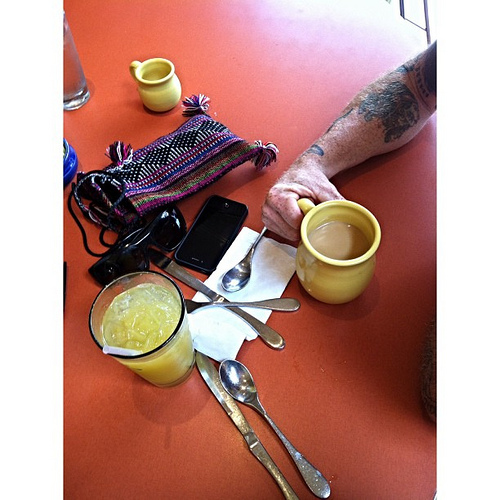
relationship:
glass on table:
[86, 268, 195, 386] [63, 0, 435, 498]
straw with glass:
[102, 345, 143, 356] [86, 268, 195, 386]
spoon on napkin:
[220, 225, 265, 291] [188, 227, 295, 362]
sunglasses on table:
[86, 205, 188, 283] [63, 0, 435, 498]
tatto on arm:
[301, 45, 435, 160] [256, 39, 438, 244]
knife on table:
[193, 350, 303, 499] [63, 0, 435, 498]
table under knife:
[63, 0, 435, 498] [193, 350, 303, 499]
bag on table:
[74, 91, 278, 223] [75, 14, 415, 483]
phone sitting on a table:
[164, 174, 253, 284] [63, 0, 435, 498]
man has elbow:
[262, 30, 465, 260] [387, 47, 437, 136]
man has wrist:
[261, 39, 437, 241] [290, 138, 343, 176]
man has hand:
[261, 39, 437, 241] [258, 162, 338, 243]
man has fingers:
[261, 39, 437, 241] [255, 189, 302, 246]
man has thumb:
[261, 39, 437, 241] [310, 182, 345, 200]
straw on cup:
[101, 342, 146, 356] [86, 267, 198, 389]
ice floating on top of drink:
[101, 282, 181, 349] [86, 270, 198, 392]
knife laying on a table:
[193, 350, 300, 500] [90, 11, 485, 103]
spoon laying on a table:
[212, 346, 333, 498] [90, 11, 485, 103]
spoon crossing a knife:
[218, 359, 331, 499] [152, 245, 289, 350]